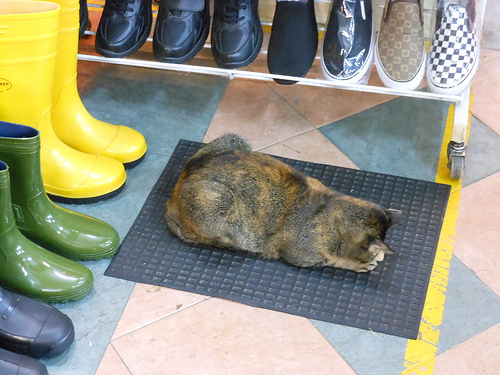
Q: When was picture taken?
A: Daytime.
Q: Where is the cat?
A: Store.